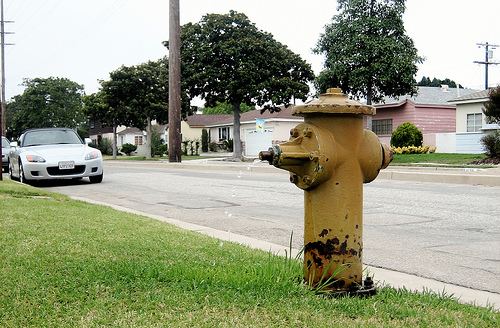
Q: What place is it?
A: It is a street.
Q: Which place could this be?
A: It is a street.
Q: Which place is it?
A: It is a street.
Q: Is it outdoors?
A: Yes, it is outdoors.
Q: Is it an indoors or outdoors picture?
A: It is outdoors.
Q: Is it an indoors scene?
A: No, it is outdoors.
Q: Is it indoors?
A: No, it is outdoors.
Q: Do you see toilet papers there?
A: No, there are no toilet papers.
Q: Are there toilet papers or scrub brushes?
A: No, there are no toilet papers or scrub brushes.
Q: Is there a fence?
A: No, there are no fences.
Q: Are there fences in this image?
A: No, there are no fences.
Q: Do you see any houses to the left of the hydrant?
A: Yes, there is a house to the left of the hydrant.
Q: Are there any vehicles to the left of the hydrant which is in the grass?
A: No, there is a house to the left of the hydrant.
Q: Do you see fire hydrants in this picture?
A: Yes, there is a fire hydrant.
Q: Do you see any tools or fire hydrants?
A: Yes, there is a fire hydrant.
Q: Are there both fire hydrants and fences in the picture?
A: No, there is a fire hydrant but no fences.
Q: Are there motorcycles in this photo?
A: No, there are no motorcycles.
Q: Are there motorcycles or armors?
A: No, there are no motorcycles or armors.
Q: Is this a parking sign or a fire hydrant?
A: This is a fire hydrant.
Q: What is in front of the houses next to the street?
A: The hydrant is in front of the houses.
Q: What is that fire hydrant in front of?
A: The fire hydrant is in front of the houses.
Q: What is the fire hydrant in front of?
A: The fire hydrant is in front of the houses.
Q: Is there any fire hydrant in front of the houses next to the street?
A: Yes, there is a fire hydrant in front of the houses.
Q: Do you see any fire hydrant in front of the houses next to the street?
A: Yes, there is a fire hydrant in front of the houses.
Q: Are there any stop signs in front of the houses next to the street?
A: No, there is a fire hydrant in front of the houses.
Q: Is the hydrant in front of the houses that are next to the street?
A: Yes, the hydrant is in front of the houses.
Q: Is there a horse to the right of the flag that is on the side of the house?
A: No, there is a fire hydrant to the right of the flag.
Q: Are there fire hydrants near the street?
A: Yes, there is a fire hydrant near the street.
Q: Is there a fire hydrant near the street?
A: Yes, there is a fire hydrant near the street.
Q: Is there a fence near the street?
A: No, there is a fire hydrant near the street.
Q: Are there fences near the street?
A: No, there is a fire hydrant near the street.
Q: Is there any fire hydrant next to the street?
A: Yes, there is a fire hydrant next to the street.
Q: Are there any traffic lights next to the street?
A: No, there is a fire hydrant next to the street.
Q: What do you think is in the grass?
A: The fire hydrant is in the grass.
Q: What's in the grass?
A: The fire hydrant is in the grass.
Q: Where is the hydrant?
A: The hydrant is in the grass.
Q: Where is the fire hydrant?
A: The hydrant is in the grass.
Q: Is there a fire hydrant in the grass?
A: Yes, there is a fire hydrant in the grass.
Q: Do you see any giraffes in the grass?
A: No, there is a fire hydrant in the grass.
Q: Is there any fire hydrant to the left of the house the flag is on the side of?
A: Yes, there is a fire hydrant to the left of the house.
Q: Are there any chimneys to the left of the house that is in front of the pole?
A: No, there is a fire hydrant to the left of the house.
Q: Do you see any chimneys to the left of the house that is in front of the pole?
A: No, there is a fire hydrant to the left of the house.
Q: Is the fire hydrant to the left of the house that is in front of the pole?
A: Yes, the fire hydrant is to the left of the house.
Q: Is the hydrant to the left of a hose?
A: No, the hydrant is to the left of the house.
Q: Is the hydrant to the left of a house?
A: Yes, the hydrant is to the left of a house.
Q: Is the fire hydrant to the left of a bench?
A: No, the fire hydrant is to the left of a house.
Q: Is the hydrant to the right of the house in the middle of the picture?
A: Yes, the hydrant is to the right of the house.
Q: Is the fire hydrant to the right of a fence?
A: No, the fire hydrant is to the right of the house.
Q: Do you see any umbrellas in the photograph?
A: No, there are no umbrellas.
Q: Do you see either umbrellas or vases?
A: No, there are no umbrellas or vases.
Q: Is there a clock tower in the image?
A: No, there are no clock towers.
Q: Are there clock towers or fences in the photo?
A: No, there are no clock towers or fences.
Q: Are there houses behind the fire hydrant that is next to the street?
A: Yes, there are houses behind the fire hydrant.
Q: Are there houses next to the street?
A: Yes, there are houses next to the street.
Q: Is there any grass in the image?
A: Yes, there is grass.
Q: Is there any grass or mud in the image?
A: Yes, there is grass.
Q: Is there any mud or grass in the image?
A: Yes, there is grass.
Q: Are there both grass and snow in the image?
A: No, there is grass but no snow.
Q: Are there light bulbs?
A: No, there are no light bulbs.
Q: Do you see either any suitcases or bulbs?
A: No, there are no bulbs or suitcases.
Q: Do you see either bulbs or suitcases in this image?
A: No, there are no bulbs or suitcases.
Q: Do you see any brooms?
A: No, there are no brooms.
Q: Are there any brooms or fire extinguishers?
A: No, there are no brooms or fire extinguishers.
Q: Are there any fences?
A: No, there are no fences.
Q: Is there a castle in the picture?
A: No, there are no castles.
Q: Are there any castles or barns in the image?
A: No, there are no castles or barns.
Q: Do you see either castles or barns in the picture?
A: No, there are no castles or barns.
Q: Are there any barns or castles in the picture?
A: No, there are no castles or barns.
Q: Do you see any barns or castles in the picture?
A: No, there are no castles or barns.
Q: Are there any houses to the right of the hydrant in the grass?
A: Yes, there is a house to the right of the fire hydrant.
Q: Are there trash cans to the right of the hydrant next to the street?
A: No, there is a house to the right of the fire hydrant.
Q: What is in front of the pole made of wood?
A: The house is in front of the pole.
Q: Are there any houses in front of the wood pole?
A: Yes, there is a house in front of the pole.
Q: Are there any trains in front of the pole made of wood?
A: No, there is a house in front of the pole.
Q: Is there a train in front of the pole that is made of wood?
A: No, there is a house in front of the pole.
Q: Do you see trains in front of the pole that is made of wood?
A: No, there is a house in front of the pole.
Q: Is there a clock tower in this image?
A: No, there are no clock towers.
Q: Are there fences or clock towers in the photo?
A: No, there are no clock towers or fences.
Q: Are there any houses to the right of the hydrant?
A: Yes, there is a house to the right of the hydrant.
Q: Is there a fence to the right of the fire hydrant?
A: No, there is a house to the right of the fire hydrant.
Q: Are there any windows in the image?
A: Yes, there is a window.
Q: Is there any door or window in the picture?
A: Yes, there is a window.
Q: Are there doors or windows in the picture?
A: Yes, there is a window.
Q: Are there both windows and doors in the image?
A: No, there is a window but no doors.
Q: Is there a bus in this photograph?
A: No, there are no buses.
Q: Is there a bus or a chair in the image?
A: No, there are no buses or chairs.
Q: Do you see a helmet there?
A: No, there are no helmets.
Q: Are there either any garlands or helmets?
A: No, there are no helmets or garlands.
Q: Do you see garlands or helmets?
A: No, there are no helmets or garlands.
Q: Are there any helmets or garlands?
A: No, there are no helmets or garlands.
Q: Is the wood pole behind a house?
A: Yes, the pole is behind a house.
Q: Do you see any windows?
A: Yes, there is a window.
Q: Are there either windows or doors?
A: Yes, there is a window.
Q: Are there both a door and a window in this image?
A: No, there is a window but no doors.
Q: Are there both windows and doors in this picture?
A: No, there is a window but no doors.